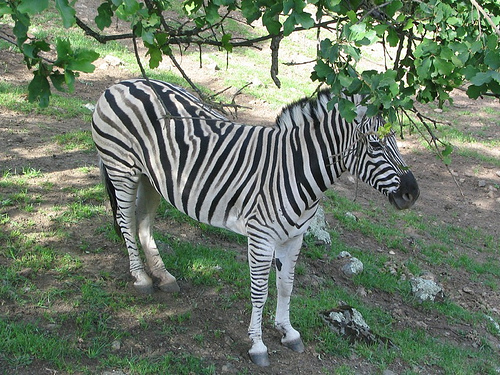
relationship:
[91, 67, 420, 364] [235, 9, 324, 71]
zebra standing under tree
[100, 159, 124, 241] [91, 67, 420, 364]
tail on zebra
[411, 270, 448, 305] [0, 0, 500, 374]
rock on ground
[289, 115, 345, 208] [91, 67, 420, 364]
neck of zebra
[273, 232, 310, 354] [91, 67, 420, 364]
front leg of zebra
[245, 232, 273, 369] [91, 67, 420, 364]
front leg of zebra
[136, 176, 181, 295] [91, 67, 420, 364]
rear leg of zebra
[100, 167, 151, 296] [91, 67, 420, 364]
leg of zebra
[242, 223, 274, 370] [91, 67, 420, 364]
leg of zebra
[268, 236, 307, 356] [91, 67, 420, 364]
leg of zebra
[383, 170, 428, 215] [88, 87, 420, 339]
nose of zebra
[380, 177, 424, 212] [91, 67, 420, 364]
nostril of zebra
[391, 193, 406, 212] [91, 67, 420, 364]
mouth of zebra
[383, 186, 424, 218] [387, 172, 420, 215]
nose and mouth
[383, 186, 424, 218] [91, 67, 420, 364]
nose of zebra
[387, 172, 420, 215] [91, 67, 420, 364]
mouth of zebra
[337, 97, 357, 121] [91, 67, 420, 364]
leaf above zebra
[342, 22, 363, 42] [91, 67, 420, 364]
leaf above zebra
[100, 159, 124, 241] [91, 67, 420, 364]
tail hanging from zebra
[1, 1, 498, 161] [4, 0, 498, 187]
leaves of tree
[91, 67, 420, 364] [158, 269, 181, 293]
zebra has hoof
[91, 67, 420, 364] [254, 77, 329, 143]
zebra has spikey mane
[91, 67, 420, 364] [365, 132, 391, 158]
zebra has eye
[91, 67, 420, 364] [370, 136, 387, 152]
zebra has eye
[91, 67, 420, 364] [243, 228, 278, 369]
zebra has leg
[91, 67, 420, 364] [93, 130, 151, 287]
zebra has leg